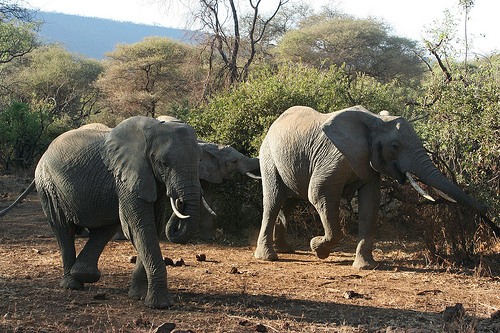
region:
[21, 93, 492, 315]
Three elephants walking together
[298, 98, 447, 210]
This one has his ears flapped out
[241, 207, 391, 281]
One foot off the ground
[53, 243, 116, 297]
Legs getting crossed up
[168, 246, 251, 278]
Elephant dung on the ground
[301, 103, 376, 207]
Light and dark contrasts on the elephant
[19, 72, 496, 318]
They are all headed in the same direction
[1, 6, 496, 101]
All small leaf trees to protect from the heat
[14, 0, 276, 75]
Mountain in the background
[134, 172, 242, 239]
Elephant has short tusks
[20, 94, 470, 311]
elephants walking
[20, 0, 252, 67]
a hill behind the trees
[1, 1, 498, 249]
trees behind the elephant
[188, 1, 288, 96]
this tree is bare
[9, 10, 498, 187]
these trees have leaves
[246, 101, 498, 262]
this elephant's truck is sticking out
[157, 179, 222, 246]
this elephant's trunk is curled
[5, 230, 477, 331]
rocks on the ground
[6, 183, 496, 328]
the grass is brown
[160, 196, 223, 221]
the elephant has white ivory tusks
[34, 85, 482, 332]
three elephants are walking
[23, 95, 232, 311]
the elephant is gray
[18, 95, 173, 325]
the elephant is wrinkled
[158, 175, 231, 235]
the elephant has tusks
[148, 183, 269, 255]
the tusks are white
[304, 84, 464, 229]
elephant's ears are wide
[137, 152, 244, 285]
the trunk is curled up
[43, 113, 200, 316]
the skin is wrinkled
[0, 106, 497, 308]
Trio elephants in the wild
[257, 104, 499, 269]
The big elephant on the right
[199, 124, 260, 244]
A partially hidden elephant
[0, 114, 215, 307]
The right white tusked elephant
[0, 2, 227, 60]
The gray hilly grounds.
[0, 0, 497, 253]
Thick bushes in the wild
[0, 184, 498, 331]
An open walking path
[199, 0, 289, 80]
The tree with joint stems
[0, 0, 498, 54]
The clear blue sky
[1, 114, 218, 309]
An elephant with a folded trunk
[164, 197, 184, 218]
The elephant's white tusk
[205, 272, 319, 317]
The ground below the elephants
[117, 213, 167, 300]
The front legs of the elephant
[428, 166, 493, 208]
The trunk of the elephant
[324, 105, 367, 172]
The right ear of the elephant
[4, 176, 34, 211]
The tail of the elephant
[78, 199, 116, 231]
The stomach of the elephant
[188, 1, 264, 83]
A tree without leaves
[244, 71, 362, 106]
Bushes behind the elephants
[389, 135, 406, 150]
The right eye of the elephant